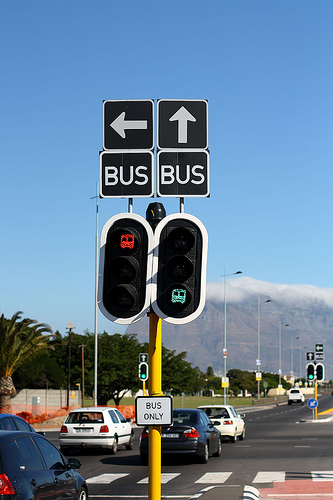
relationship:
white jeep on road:
[282, 385, 311, 404] [247, 405, 281, 437]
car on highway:
[197, 404, 244, 441] [0, 394, 332, 499]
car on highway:
[139, 408, 222, 461] [81, 390, 328, 498]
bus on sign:
[104, 162, 149, 189] [98, 90, 210, 201]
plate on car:
[69, 424, 101, 436] [54, 398, 139, 459]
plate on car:
[152, 427, 188, 439] [139, 396, 231, 467]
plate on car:
[207, 418, 226, 430] [191, 397, 256, 448]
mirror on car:
[67, 456, 81, 470] [0, 430, 88, 498]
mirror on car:
[210, 419, 221, 426] [139, 408, 222, 461]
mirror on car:
[237, 412, 246, 419] [197, 404, 244, 441]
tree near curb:
[11, 329, 199, 392] [31, 426, 60, 432]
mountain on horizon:
[123, 274, 330, 379] [147, 343, 332, 392]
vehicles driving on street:
[0, 388, 322, 496] [26, 385, 329, 497]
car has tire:
[54, 398, 139, 459] [231, 431, 237, 442]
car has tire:
[139, 408, 222, 461] [202, 444, 208, 464]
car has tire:
[197, 404, 244, 441] [109, 440, 118, 453]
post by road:
[141, 312, 168, 498] [243, 398, 332, 465]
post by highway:
[221, 264, 227, 409] [81, 390, 328, 498]